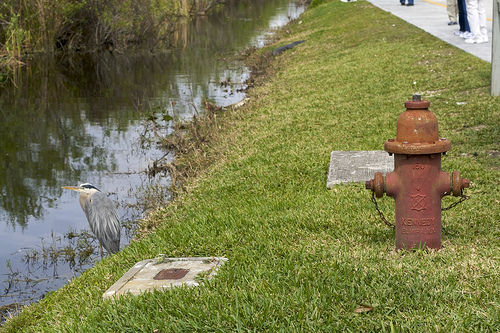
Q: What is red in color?
A: The fire hydrant.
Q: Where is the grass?
A: Next to the hydrant.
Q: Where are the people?
A: Behind the hydrant.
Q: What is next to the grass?
A: The water.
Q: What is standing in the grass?
A: A bird.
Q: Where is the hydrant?
A: In the ground.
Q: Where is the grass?
A: On the ground.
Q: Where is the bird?
A: By the water.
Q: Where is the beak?
A: On the bird.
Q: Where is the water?
A: In the canal.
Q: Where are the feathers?
A: On the bird.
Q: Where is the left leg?
A: On the bird.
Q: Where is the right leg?
A: On the bird.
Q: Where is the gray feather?
A: On the bird.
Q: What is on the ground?
A: Grass.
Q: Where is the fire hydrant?
A: In grass.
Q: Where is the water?
A: Bottom of grass.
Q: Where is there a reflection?
A: In water.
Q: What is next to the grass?
A: Sidewalk.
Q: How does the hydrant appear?
A: Red and rusty.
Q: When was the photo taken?
A: In the daytime.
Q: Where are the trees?
A: Side of water.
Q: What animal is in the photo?
A: Bird.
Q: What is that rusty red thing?
A: Fire hydrant.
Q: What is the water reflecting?
A: Trees.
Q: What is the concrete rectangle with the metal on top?
A: Water meter.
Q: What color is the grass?
A: Green.